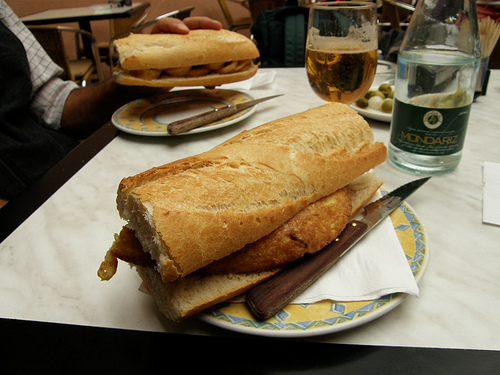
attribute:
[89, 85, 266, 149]
plate — yellow, white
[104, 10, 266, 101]
sandwich — large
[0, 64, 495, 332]
paper — white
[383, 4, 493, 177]
bottle — clear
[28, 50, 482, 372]
table — black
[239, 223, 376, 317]
handle — wood, wooden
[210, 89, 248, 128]
designs — blue